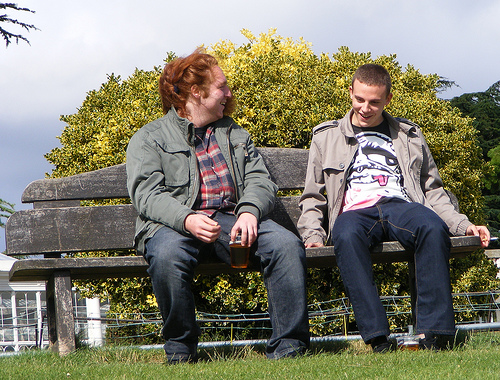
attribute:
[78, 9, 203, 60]
sky — grey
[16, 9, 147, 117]
clouds — white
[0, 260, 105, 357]
building — white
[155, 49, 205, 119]
hair — orange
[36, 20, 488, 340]
tree — green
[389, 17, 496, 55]
sky — blue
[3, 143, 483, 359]
bench — old, grey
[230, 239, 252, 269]
drink — brown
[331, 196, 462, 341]
jeans — dark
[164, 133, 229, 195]
shirt — red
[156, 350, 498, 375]
grass — green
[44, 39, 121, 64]
clouds — white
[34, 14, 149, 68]
clouds — white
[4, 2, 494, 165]
sky — blue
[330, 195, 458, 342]
pants — jean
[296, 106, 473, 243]
jacket — grey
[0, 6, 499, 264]
sky — blue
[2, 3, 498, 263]
clouds — white